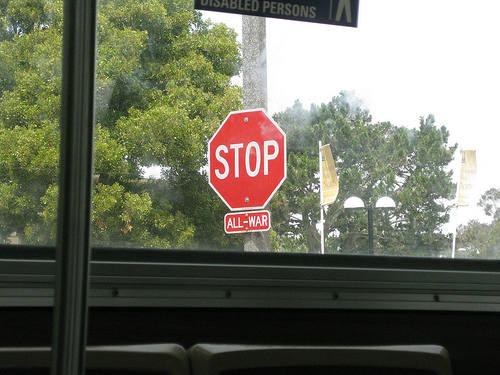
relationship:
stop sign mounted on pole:
[205, 106, 287, 210] [238, 13, 273, 254]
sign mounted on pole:
[222, 209, 272, 234] [238, 13, 273, 254]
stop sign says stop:
[205, 106, 287, 210] [214, 140, 279, 178]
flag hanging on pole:
[318, 143, 340, 208] [317, 137, 325, 254]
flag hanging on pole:
[456, 146, 478, 209] [449, 144, 460, 257]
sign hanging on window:
[194, 1, 361, 28] [91, 2, 499, 261]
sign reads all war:
[222, 209, 272, 234] [225, 213, 267, 229]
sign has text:
[194, 1, 361, 28] [200, 1, 315, 21]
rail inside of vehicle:
[51, 1, 98, 374] [0, 1, 497, 374]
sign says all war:
[222, 209, 272, 234] [225, 213, 267, 229]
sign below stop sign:
[222, 209, 272, 234] [205, 106, 287, 210]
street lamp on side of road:
[341, 193, 398, 255] [89, 238, 499, 260]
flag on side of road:
[318, 143, 340, 208] [89, 238, 499, 260]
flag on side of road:
[456, 146, 478, 209] [89, 238, 499, 260]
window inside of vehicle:
[91, 2, 499, 261] [0, 1, 497, 374]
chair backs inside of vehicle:
[1, 338, 455, 374] [0, 1, 497, 374]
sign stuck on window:
[194, 1, 361, 28] [91, 2, 499, 261]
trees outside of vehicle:
[0, 0, 498, 257] [0, 1, 497, 374]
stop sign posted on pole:
[205, 106, 287, 210] [238, 13, 273, 254]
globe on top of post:
[373, 193, 396, 212] [366, 207, 377, 255]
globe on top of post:
[339, 195, 365, 210] [366, 207, 377, 255]